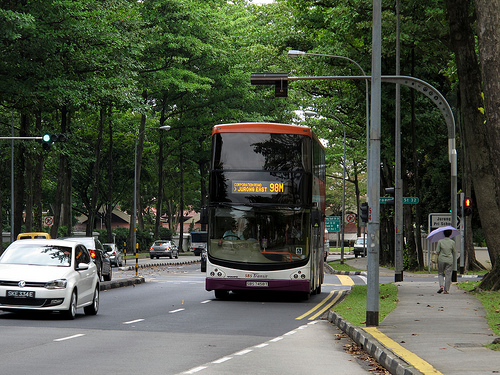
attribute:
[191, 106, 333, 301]
bus — red, rd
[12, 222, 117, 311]
car — white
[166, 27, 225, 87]
leaves — green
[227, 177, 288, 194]
sign — yellow